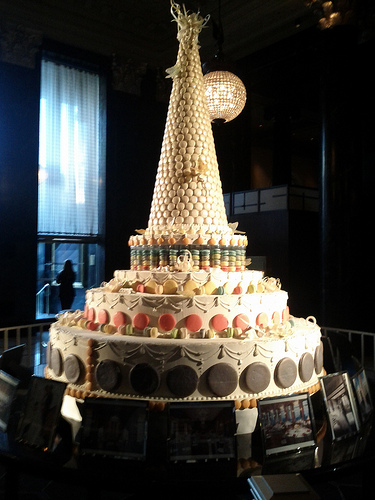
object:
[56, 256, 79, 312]
person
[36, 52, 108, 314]
window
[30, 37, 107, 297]
curtain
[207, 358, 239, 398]
cookies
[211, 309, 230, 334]
candies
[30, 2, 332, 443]
cake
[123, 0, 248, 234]
pointed top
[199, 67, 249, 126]
bulb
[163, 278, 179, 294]
candies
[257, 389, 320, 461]
picture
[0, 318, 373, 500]
table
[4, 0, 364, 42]
ceiling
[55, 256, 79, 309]
silhouette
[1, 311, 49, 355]
railing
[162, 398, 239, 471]
pictures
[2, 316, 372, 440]
fencing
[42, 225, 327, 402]
five layers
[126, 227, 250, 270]
last level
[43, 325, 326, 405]
first layer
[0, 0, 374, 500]
room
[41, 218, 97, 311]
outside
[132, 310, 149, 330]
circles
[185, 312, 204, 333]
orange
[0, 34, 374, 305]
background